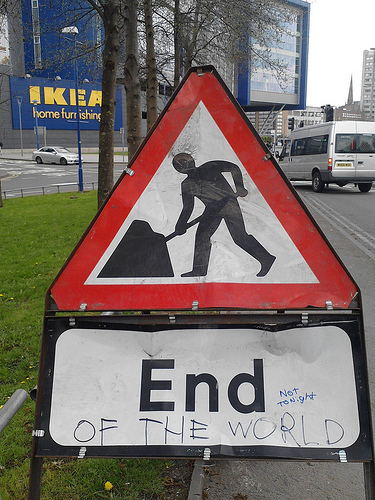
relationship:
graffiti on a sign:
[63, 424, 345, 440] [42, 54, 365, 479]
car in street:
[31, 142, 83, 171] [2, 158, 373, 498]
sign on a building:
[19, 69, 142, 140] [62, 39, 291, 111]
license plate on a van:
[334, 160, 357, 168] [324, 145, 354, 202]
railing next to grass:
[0, 183, 100, 201] [1, 188, 217, 498]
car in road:
[272, 120, 375, 193] [200, 179, 374, 498]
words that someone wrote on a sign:
[68, 418, 351, 448] [34, 48, 350, 427]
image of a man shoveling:
[108, 148, 253, 285] [172, 151, 277, 276]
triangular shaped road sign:
[55, 113, 343, 309] [33, 56, 367, 324]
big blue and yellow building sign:
[2, 82, 128, 137] [18, 69, 127, 141]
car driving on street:
[272, 120, 375, 193] [326, 173, 370, 221]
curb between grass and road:
[183, 458, 208, 493] [210, 459, 365, 493]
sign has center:
[42, 64, 362, 312] [90, 97, 325, 286]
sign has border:
[42, 64, 362, 312] [39, 66, 362, 321]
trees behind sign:
[8, 0, 309, 212] [36, 65, 371, 498]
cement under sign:
[148, 350, 363, 495] [47, 113, 358, 467]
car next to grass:
[26, 142, 83, 172] [58, 471, 92, 496]